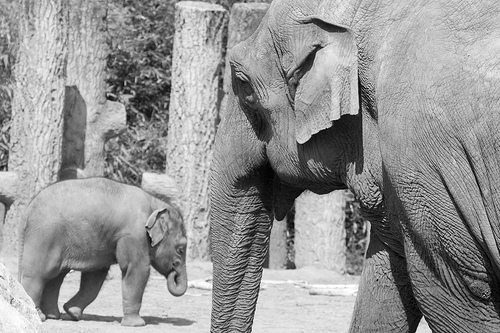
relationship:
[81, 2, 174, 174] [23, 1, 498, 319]
forest behind elephants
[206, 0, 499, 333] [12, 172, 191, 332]
elephant with baby elephant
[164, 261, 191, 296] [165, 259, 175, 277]
baby trunk curled into mouth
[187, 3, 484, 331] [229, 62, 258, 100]
elephant has eye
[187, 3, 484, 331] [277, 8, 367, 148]
elephant has ear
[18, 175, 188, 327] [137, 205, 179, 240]
baby elephant has ear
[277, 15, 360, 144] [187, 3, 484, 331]
ear of elephant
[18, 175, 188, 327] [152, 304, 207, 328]
baby elephant in ground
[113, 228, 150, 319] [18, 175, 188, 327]
leg of baby elephant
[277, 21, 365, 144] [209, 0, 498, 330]
ear of elephant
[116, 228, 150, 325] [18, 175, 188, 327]
leg of baby elephant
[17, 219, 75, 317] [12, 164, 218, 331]
legs of elephant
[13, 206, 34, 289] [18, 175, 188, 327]
tail of baby elephant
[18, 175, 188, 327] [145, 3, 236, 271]
baby elephant near tree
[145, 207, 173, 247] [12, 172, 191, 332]
ear of baby elephant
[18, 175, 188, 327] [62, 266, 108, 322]
baby elephant raising leg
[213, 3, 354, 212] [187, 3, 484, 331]
face of elephant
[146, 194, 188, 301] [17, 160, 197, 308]
face of elephant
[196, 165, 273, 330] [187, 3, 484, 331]
trunk of elephant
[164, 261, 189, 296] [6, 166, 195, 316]
trunk of elephant